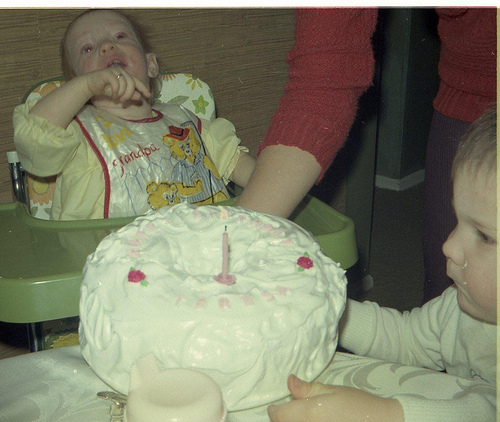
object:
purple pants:
[420, 111, 471, 309]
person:
[232, 5, 498, 308]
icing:
[81, 203, 346, 347]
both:
[10, 9, 500, 421]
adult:
[230, 7, 496, 310]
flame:
[216, 203, 230, 224]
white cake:
[130, 285, 350, 414]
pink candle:
[220, 225, 230, 272]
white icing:
[88, 209, 205, 335]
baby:
[265, 103, 498, 420]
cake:
[75, 201, 350, 416]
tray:
[0, 168, 360, 327]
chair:
[0, 72, 361, 354]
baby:
[10, 8, 258, 259]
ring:
[115, 73, 123, 80]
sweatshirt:
[332, 278, 499, 421]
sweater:
[253, 8, 498, 188]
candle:
[211, 223, 238, 286]